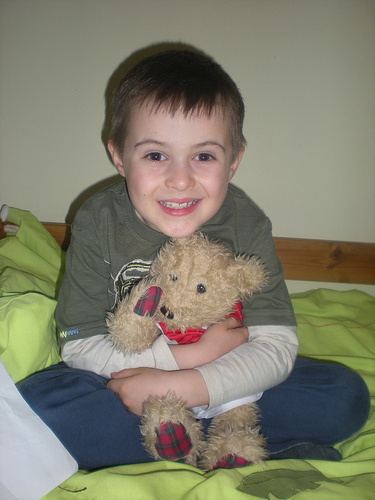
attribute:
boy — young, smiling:
[13, 51, 370, 469]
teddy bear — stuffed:
[108, 235, 268, 472]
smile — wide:
[154, 197, 201, 218]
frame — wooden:
[39, 221, 372, 287]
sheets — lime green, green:
[3, 204, 372, 498]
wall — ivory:
[3, 2, 374, 297]